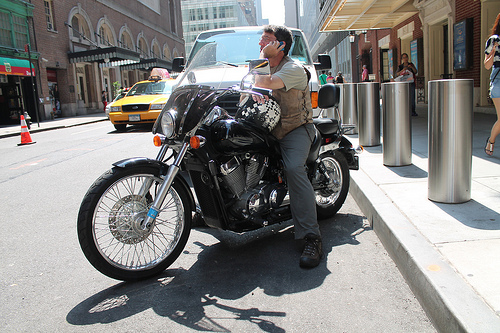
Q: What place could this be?
A: It is a city.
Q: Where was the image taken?
A: It was taken at the city.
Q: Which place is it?
A: It is a city.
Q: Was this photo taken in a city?
A: Yes, it was taken in a city.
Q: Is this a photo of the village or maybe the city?
A: It is showing the city.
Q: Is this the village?
A: No, it is the city.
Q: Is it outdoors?
A: Yes, it is outdoors.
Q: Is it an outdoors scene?
A: Yes, it is outdoors.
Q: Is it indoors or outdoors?
A: It is outdoors.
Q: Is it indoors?
A: No, it is outdoors.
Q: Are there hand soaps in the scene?
A: No, there are no hand soaps.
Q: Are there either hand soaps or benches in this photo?
A: No, there are no hand soaps or benches.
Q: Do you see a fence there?
A: No, there are no fences.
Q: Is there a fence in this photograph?
A: No, there are no fences.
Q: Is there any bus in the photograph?
A: No, there are no buses.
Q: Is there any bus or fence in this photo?
A: No, there are no buses or fences.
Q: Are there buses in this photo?
A: No, there are no buses.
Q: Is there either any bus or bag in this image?
A: No, there are no buses or bags.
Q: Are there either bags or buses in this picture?
A: No, there are no buses or bags.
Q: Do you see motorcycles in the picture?
A: Yes, there is a motorcycle.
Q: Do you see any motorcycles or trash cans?
A: Yes, there is a motorcycle.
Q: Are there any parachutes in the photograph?
A: No, there are no parachutes.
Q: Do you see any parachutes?
A: No, there are no parachutes.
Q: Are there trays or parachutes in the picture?
A: No, there are no parachutes or trays.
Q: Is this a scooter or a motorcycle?
A: This is a motorcycle.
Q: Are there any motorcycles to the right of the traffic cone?
A: Yes, there is a motorcycle to the right of the traffic cone.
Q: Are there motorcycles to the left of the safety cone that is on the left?
A: No, the motorcycle is to the right of the cone.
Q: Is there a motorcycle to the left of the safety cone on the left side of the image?
A: No, the motorcycle is to the right of the cone.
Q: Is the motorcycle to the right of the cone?
A: Yes, the motorcycle is to the right of the cone.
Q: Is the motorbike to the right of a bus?
A: No, the motorbike is to the right of the cone.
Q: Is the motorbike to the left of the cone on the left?
A: No, the motorbike is to the right of the traffic cone.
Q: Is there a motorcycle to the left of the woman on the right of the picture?
A: Yes, there is a motorcycle to the left of the woman.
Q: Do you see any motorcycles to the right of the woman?
A: No, the motorcycle is to the left of the woman.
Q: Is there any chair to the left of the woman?
A: No, there is a motorcycle to the left of the woman.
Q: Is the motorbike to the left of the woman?
A: Yes, the motorbike is to the left of the woman.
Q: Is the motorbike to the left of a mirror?
A: No, the motorbike is to the left of the woman.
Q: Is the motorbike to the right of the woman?
A: No, the motorbike is to the left of the woman.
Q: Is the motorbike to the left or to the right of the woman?
A: The motorbike is to the left of the woman.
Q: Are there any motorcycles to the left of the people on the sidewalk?
A: Yes, there is a motorcycle to the left of the people.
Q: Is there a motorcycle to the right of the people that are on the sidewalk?
A: No, the motorcycle is to the left of the people.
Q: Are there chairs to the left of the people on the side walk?
A: No, there is a motorcycle to the left of the people.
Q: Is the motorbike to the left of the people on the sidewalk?
A: Yes, the motorbike is to the left of the people.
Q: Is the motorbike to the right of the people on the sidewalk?
A: No, the motorbike is to the left of the people.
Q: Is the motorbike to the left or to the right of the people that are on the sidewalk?
A: The motorbike is to the left of the people.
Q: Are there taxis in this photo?
A: Yes, there is a taxi.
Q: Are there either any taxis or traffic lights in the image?
A: Yes, there is a taxi.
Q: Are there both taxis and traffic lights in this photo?
A: No, there is a taxi but no traffic lights.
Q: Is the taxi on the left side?
A: Yes, the taxi is on the left of the image.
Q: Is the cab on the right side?
A: No, the cab is on the left of the image.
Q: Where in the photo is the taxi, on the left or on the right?
A: The taxi is on the left of the image.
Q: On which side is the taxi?
A: The taxi is on the left of the image.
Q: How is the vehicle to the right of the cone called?
A: The vehicle is a taxi.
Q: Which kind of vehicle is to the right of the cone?
A: The vehicle is a taxi.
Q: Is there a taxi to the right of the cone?
A: Yes, there is a taxi to the right of the cone.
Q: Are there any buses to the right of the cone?
A: No, there is a taxi to the right of the cone.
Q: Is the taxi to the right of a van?
A: No, the taxi is to the right of the cone.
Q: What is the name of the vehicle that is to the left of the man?
A: The vehicle is a taxi.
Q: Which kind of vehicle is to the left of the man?
A: The vehicle is a taxi.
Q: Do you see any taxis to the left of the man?
A: Yes, there is a taxi to the left of the man.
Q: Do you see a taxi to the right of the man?
A: No, the taxi is to the left of the man.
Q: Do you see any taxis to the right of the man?
A: No, the taxi is to the left of the man.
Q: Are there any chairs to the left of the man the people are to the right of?
A: No, there is a taxi to the left of the man.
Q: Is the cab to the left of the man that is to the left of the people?
A: Yes, the cab is to the left of the man.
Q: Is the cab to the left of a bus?
A: No, the cab is to the left of the man.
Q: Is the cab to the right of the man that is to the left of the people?
A: No, the cab is to the left of the man.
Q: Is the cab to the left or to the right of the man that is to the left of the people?
A: The cab is to the left of the man.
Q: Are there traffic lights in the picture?
A: No, there are no traffic lights.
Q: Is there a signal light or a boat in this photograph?
A: No, there are no traffic lights or boats.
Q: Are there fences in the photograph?
A: No, there are no fences.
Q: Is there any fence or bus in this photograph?
A: No, there are no fences or buses.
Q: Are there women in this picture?
A: Yes, there is a woman.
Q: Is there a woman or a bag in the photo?
A: Yes, there is a woman.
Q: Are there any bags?
A: No, there are no bags.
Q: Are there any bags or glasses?
A: No, there are no bags or glasses.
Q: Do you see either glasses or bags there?
A: No, there are no bags or glasses.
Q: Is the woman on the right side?
A: Yes, the woman is on the right of the image.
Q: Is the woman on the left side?
A: No, the woman is on the right of the image.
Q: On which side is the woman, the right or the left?
A: The woman is on the right of the image.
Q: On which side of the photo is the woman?
A: The woman is on the right of the image.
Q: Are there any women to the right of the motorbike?
A: Yes, there is a woman to the right of the motorbike.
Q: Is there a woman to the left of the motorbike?
A: No, the woman is to the right of the motorbike.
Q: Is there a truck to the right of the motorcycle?
A: No, there is a woman to the right of the motorcycle.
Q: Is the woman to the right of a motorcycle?
A: Yes, the woman is to the right of a motorcycle.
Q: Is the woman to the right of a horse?
A: No, the woman is to the right of a motorcycle.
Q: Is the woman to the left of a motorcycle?
A: No, the woman is to the right of a motorcycle.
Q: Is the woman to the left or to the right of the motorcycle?
A: The woman is to the right of the motorcycle.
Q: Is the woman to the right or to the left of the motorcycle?
A: The woman is to the right of the motorcycle.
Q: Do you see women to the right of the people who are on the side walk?
A: Yes, there is a woman to the right of the people.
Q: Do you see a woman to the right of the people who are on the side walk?
A: Yes, there is a woman to the right of the people.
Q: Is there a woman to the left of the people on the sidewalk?
A: No, the woman is to the right of the people.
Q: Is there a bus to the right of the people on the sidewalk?
A: No, there is a woman to the right of the people.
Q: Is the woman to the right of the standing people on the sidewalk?
A: Yes, the woman is to the right of the people.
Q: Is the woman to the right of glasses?
A: No, the woman is to the right of the people.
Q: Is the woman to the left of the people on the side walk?
A: No, the woman is to the right of the people.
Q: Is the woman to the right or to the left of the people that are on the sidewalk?
A: The woman is to the right of the people.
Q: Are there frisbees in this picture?
A: No, there are no frisbees.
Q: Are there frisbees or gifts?
A: No, there are no frisbees or gifts.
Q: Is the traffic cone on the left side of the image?
A: Yes, the traffic cone is on the left of the image.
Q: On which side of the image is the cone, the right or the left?
A: The cone is on the left of the image.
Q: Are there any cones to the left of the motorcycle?
A: Yes, there is a cone to the left of the motorcycle.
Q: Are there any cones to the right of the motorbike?
A: No, the cone is to the left of the motorbike.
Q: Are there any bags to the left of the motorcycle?
A: No, there is a cone to the left of the motorcycle.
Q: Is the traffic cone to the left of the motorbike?
A: Yes, the traffic cone is to the left of the motorbike.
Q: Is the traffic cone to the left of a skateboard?
A: No, the traffic cone is to the left of the motorbike.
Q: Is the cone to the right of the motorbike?
A: No, the cone is to the left of the motorbike.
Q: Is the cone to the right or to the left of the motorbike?
A: The cone is to the left of the motorbike.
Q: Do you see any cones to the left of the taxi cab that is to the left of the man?
A: Yes, there is a cone to the left of the taxi.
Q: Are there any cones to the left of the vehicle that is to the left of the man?
A: Yes, there is a cone to the left of the taxi.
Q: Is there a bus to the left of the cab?
A: No, there is a cone to the left of the cab.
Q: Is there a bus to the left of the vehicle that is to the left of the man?
A: No, there is a cone to the left of the cab.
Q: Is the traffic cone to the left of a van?
A: No, the traffic cone is to the left of the cab.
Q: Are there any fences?
A: No, there are no fences.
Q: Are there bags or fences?
A: No, there are no fences or bags.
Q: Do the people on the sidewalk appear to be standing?
A: Yes, the people are standing.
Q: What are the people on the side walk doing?
A: The people are standing.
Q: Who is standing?
A: The people are standing.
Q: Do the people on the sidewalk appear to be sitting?
A: No, the people are standing.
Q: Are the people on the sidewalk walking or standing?
A: The people are standing.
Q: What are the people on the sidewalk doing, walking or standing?
A: The people are standing.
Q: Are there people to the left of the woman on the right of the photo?
A: Yes, there are people to the left of the woman.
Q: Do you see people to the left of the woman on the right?
A: Yes, there are people to the left of the woman.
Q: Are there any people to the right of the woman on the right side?
A: No, the people are to the left of the woman.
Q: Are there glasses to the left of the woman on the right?
A: No, there are people to the left of the woman.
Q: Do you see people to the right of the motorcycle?
A: Yes, there are people to the right of the motorcycle.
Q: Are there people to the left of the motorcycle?
A: No, the people are to the right of the motorcycle.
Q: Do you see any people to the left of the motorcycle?
A: No, the people are to the right of the motorcycle.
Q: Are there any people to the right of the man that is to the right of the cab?
A: Yes, there are people to the right of the man.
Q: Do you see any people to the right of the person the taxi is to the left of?
A: Yes, there are people to the right of the man.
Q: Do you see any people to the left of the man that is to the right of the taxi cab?
A: No, the people are to the right of the man.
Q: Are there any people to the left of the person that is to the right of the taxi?
A: No, the people are to the right of the man.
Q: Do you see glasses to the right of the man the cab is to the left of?
A: No, there are people to the right of the man.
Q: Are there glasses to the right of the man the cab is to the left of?
A: No, there are people to the right of the man.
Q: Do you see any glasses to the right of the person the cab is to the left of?
A: No, there are people to the right of the man.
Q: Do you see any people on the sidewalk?
A: Yes, there are people on the sidewalk.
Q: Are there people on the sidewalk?
A: Yes, there are people on the sidewalk.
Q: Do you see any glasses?
A: No, there are no glasses.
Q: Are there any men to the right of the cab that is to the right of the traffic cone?
A: Yes, there is a man to the right of the taxi.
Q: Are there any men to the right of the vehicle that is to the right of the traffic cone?
A: Yes, there is a man to the right of the taxi.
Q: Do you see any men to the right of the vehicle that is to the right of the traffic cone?
A: Yes, there is a man to the right of the taxi.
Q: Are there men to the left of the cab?
A: No, the man is to the right of the cab.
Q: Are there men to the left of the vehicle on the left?
A: No, the man is to the right of the cab.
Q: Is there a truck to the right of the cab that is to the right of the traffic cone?
A: No, there is a man to the right of the cab.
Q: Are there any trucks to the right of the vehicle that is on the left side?
A: No, there is a man to the right of the cab.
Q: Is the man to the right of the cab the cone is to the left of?
A: Yes, the man is to the right of the cab.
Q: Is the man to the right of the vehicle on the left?
A: Yes, the man is to the right of the cab.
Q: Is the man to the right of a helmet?
A: No, the man is to the right of the cab.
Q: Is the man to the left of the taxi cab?
A: No, the man is to the right of the taxi cab.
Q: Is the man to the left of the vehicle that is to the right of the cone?
A: No, the man is to the right of the taxi cab.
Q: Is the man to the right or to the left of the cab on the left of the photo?
A: The man is to the right of the taxi.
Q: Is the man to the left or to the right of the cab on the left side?
A: The man is to the right of the taxi.